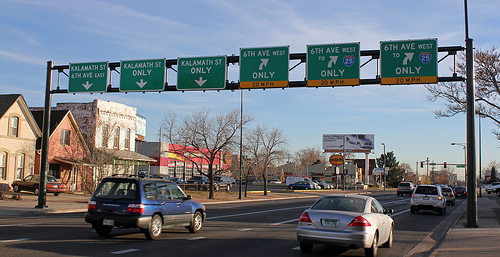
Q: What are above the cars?
A: Signs.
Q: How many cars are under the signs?
A: Two.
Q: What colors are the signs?
A: Green and white.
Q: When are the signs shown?
A: Daytime.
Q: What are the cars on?
A: Street.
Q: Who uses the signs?
A: Drivers.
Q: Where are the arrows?
A: On the signs.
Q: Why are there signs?
A: To give direction.